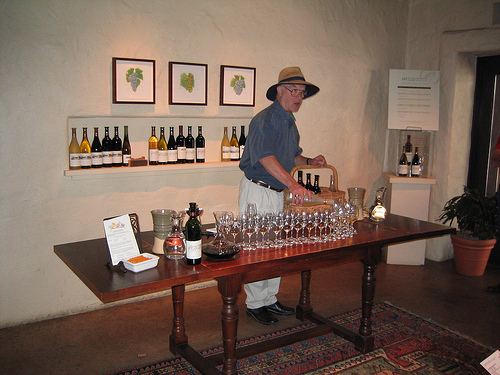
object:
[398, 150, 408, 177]
bottle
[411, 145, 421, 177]
bottle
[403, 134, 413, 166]
bottle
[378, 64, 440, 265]
stand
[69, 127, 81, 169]
beverage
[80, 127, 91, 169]
beverage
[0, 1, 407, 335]
wall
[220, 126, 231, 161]
wines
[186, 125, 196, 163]
wines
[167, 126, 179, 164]
wines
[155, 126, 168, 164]
wines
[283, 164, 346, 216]
basket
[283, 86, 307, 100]
glasses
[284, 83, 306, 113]
face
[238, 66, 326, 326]
man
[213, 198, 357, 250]
glasses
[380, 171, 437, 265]
pedestal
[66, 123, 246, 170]
wine bottles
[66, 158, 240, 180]
shelf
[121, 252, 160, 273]
container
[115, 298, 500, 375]
carpet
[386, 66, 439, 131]
poster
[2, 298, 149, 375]
floor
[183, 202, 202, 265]
wine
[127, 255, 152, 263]
pencils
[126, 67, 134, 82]
leaves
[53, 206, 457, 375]
tables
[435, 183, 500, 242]
plant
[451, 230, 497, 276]
planter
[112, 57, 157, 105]
poster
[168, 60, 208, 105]
poster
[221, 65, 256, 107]
poster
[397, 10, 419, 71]
corner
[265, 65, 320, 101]
hat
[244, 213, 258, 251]
wine glass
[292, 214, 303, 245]
wine glass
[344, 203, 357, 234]
wine glass